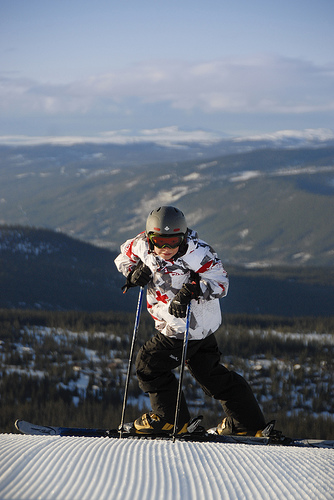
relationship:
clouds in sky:
[6, 52, 319, 126] [2, 3, 330, 132]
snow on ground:
[66, 364, 99, 398] [5, 315, 330, 436]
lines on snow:
[29, 453, 298, 494] [3, 434, 332, 500]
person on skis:
[116, 199, 266, 423] [10, 421, 321, 442]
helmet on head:
[142, 205, 191, 232] [143, 205, 190, 265]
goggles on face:
[145, 233, 186, 247] [147, 229, 185, 266]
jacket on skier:
[108, 232, 234, 339] [116, 199, 266, 423]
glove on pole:
[163, 284, 202, 317] [168, 303, 195, 439]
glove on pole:
[126, 267, 153, 294] [114, 289, 143, 433]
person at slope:
[116, 199, 266, 423] [3, 434, 332, 500]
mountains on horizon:
[12, 144, 333, 250] [5, 137, 333, 145]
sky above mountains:
[2, 3, 330, 132] [12, 144, 333, 250]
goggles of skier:
[145, 233, 186, 247] [116, 199, 266, 423]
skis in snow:
[10, 421, 321, 442] [3, 434, 332, 500]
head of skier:
[143, 205, 190, 265] [116, 199, 266, 423]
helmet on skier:
[142, 205, 191, 232] [116, 199, 266, 423]